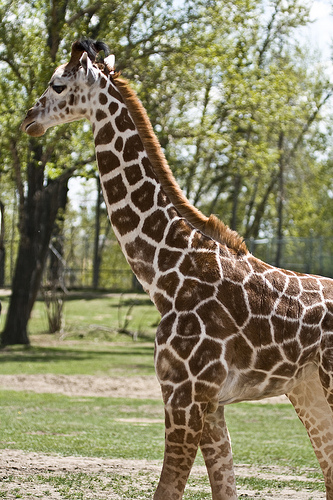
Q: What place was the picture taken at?
A: It was taken at the road.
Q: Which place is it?
A: It is a road.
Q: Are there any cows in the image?
A: No, there are no cows.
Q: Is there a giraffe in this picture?
A: Yes, there is a giraffe.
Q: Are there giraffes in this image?
A: Yes, there is a giraffe.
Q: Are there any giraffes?
A: Yes, there is a giraffe.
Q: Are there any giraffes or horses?
A: Yes, there is a giraffe.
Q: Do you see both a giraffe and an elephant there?
A: No, there is a giraffe but no elephants.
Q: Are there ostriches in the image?
A: No, there are no ostriches.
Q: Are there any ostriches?
A: No, there are no ostriches.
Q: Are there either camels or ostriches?
A: No, there are no ostriches or camels.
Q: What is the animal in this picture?
A: The animal is a giraffe.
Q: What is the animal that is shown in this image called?
A: The animal is a giraffe.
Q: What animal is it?
A: The animal is a giraffe.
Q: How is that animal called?
A: That is a giraffe.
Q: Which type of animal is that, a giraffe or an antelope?
A: That is a giraffe.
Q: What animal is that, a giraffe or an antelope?
A: That is a giraffe.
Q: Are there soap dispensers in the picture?
A: No, there are no soap dispensers.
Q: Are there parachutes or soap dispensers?
A: No, there are no soap dispensers or parachutes.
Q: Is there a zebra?
A: No, there are no zebras.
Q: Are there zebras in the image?
A: No, there are no zebras.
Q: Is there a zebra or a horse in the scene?
A: No, there are no zebras or horses.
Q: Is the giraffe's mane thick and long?
A: No, the mane is thick but short.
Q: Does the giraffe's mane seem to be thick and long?
A: No, the mane is thick but short.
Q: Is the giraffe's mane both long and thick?
A: No, the mane is thick but short.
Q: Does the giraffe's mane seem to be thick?
A: Yes, the mane is thick.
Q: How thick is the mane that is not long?
A: The mane is thick.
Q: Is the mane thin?
A: No, the mane is thick.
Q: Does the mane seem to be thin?
A: No, the mane is thick.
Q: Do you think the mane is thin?
A: No, the mane is thick.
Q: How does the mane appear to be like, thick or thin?
A: The mane is thick.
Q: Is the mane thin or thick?
A: The mane is thick.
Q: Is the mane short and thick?
A: Yes, the mane is short and thick.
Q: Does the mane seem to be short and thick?
A: Yes, the mane is short and thick.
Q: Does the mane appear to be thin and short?
A: No, the mane is short but thick.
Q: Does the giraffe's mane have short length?
A: Yes, the mane is short.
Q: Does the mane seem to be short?
A: Yes, the mane is short.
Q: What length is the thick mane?
A: The mane is short.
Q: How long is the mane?
A: The mane is short.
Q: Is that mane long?
A: No, the mane is short.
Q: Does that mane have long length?
A: No, the mane is short.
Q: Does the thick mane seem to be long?
A: No, the mane is short.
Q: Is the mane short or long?
A: The mane is short.